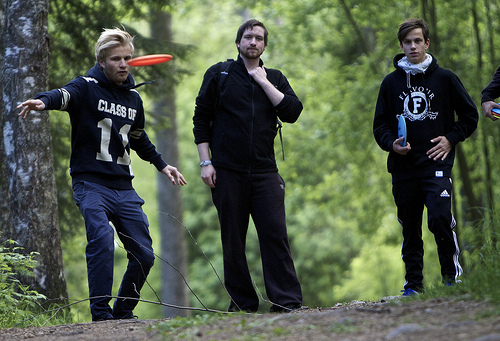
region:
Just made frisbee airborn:
[17, 22, 179, 322]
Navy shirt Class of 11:
[85, 93, 155, 194]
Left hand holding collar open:
[194, 17, 297, 108]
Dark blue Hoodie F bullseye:
[383, 21, 449, 131]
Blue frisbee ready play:
[367, 84, 419, 190]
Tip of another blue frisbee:
[477, 64, 498, 150]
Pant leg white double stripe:
[427, 163, 472, 290]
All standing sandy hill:
[12, 201, 495, 336]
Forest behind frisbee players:
[285, 5, 401, 253]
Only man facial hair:
[224, 19, 291, 68]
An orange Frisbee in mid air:
[116, 42, 179, 72]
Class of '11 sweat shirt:
[81, 84, 176, 182]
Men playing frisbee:
[21, 22, 497, 319]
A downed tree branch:
[54, 241, 377, 333]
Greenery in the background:
[283, 29, 409, 191]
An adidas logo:
[434, 183, 460, 211]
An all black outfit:
[203, 14, 328, 331]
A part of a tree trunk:
[3, 35, 73, 295]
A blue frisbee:
[392, 101, 419, 148]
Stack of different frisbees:
[487, 98, 497, 123]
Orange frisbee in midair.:
[128, 54, 172, 67]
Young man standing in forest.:
[370, 21, 478, 296]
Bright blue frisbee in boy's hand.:
[395, 115, 408, 146]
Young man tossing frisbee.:
[12, 28, 186, 325]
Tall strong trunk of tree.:
[149, 1, 191, 315]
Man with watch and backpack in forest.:
[192, 18, 309, 314]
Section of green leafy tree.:
[310, 79, 370, 301]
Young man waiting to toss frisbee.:
[372, 18, 480, 298]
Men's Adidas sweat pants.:
[390, 165, 463, 291]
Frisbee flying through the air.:
[126, 51, 173, 66]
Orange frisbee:
[125, 51, 172, 63]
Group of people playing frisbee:
[15, 20, 475, 315]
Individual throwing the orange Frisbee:
[12, 25, 182, 320]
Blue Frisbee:
[397, 110, 408, 143]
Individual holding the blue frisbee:
[368, 21, 479, 296]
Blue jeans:
[70, 177, 160, 307]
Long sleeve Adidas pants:
[390, 172, 460, 282]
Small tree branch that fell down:
[3, 238, 229, 324]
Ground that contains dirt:
[1, 293, 497, 338]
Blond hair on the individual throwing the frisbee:
[86, 23, 134, 58]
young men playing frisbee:
[23, 13, 474, 318]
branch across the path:
[45, 206, 335, 321]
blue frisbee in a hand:
[366, 85, 441, 171]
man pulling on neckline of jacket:
[196, 22, 301, 122]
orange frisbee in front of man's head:
[11, 15, 186, 187]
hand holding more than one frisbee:
[477, 91, 494, 126]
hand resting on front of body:
[415, 110, 480, 200]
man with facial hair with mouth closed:
[210, 15, 285, 80]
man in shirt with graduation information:
[45, 26, 177, 191]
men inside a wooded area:
[52, 15, 467, 325]